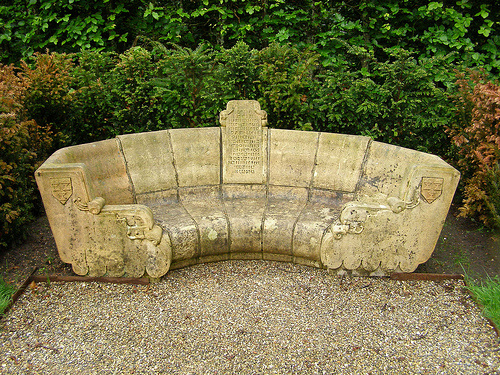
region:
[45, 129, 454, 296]
large and stone bench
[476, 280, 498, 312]
green grass near bench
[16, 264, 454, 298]
brown frame around stone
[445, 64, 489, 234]
brown bushes on sides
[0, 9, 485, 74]
thick and green bushes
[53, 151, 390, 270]
bench is grey and weathered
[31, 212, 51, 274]
dark stone behind bench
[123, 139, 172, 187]
gray stone on bench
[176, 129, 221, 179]
gray stone on bench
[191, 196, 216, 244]
gray stone on bench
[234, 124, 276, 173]
gray stone on bench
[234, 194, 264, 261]
gray stone on bench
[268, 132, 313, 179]
gray stone on bench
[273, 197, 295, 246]
gray stone on bench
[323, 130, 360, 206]
gray stone on bench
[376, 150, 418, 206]
gray stone on bench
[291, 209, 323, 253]
gray stone on bench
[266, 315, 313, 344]
brown and white rocks on ground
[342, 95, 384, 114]
green bushes behind couch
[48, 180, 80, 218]
stone plaque on stone sofa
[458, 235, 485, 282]
black dirt behind sofa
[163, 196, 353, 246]
dirty spots on stone sofa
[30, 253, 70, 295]
metal frame in front of sofa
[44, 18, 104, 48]
trees in back with an abundance of leaves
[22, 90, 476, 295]
this is a stone bench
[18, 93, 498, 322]
a cement bench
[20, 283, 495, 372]
gravel on the ground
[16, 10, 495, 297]
the bench is in front of a bush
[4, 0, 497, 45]
this is a green bush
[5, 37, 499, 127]
here are some hedges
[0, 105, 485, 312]
a decorative bench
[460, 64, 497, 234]
these leaves are orange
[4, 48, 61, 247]
leaves on this bush are orange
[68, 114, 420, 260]
brown bench on stone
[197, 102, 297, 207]
stone tablet on bench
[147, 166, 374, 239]
bench is grey and weathered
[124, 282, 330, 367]
brown stone in front of bench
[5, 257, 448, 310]
brown wooden frame around stone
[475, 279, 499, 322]
green grass near stone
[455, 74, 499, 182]
brown bush near bench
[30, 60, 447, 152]
small green bushes behind bench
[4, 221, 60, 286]
brown stone behind bench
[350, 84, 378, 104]
green leaves in the tree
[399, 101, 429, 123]
green leaves in the tree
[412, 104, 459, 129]
green leaves in the tree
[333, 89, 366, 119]
green leaves in the tree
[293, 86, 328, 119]
green leaves in the tree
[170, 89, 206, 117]
green leaves in the tree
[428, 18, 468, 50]
green leaves in the tree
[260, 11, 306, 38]
green leaves in the tree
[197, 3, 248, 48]
green leaves in the tree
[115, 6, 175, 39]
green leaves in the tree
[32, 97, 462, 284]
A curved concrete bench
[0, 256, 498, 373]
Rocks on the ground in a wooden perimeter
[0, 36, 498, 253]
Green and orange bushes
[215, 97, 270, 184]
An inscription in a stone bench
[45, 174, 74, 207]
A symbol on a stone bench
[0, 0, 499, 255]
Foliage behind the stone bench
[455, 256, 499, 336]
Patch of green grass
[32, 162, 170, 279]
Carved arm of a stone bench